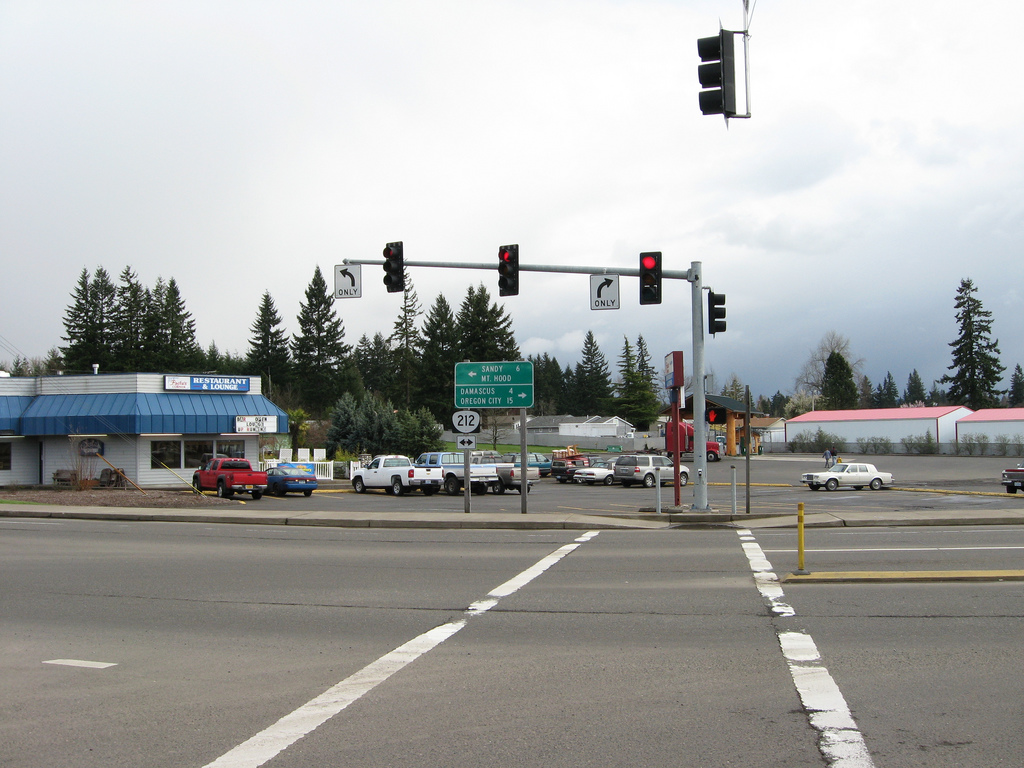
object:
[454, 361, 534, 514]
street sign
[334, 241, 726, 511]
traffic light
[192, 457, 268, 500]
pickup truck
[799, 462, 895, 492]
white car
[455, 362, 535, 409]
road sign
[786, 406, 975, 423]
roof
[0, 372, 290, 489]
building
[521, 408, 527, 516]
post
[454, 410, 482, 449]
post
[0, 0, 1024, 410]
sky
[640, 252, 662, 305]
traffic light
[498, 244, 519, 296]
traffic light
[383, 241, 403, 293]
traffic light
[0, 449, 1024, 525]
lot